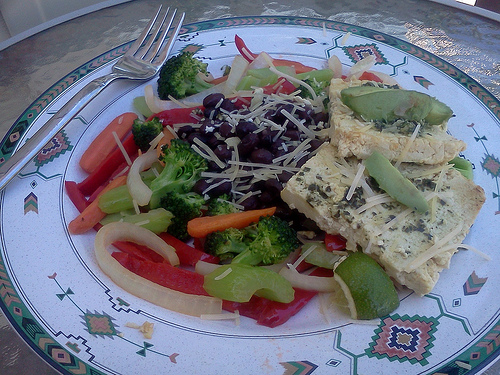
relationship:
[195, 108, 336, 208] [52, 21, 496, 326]
salad on plate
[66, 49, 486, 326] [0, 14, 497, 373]
salad on plate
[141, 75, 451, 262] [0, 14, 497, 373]
salad on plate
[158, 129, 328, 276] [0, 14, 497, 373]
salad on plate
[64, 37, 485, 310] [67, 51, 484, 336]
food topping dish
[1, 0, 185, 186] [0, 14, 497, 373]
fork resting on plate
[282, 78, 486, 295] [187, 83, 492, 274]
tofu with cheese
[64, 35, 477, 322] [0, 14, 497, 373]
vegatables on plate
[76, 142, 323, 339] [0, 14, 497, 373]
peppers on plate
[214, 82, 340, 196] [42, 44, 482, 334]
cheese on salad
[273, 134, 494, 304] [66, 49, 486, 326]
tofu on salad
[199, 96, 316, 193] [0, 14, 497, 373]
beans on plate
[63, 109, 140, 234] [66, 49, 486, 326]
carrots in salad